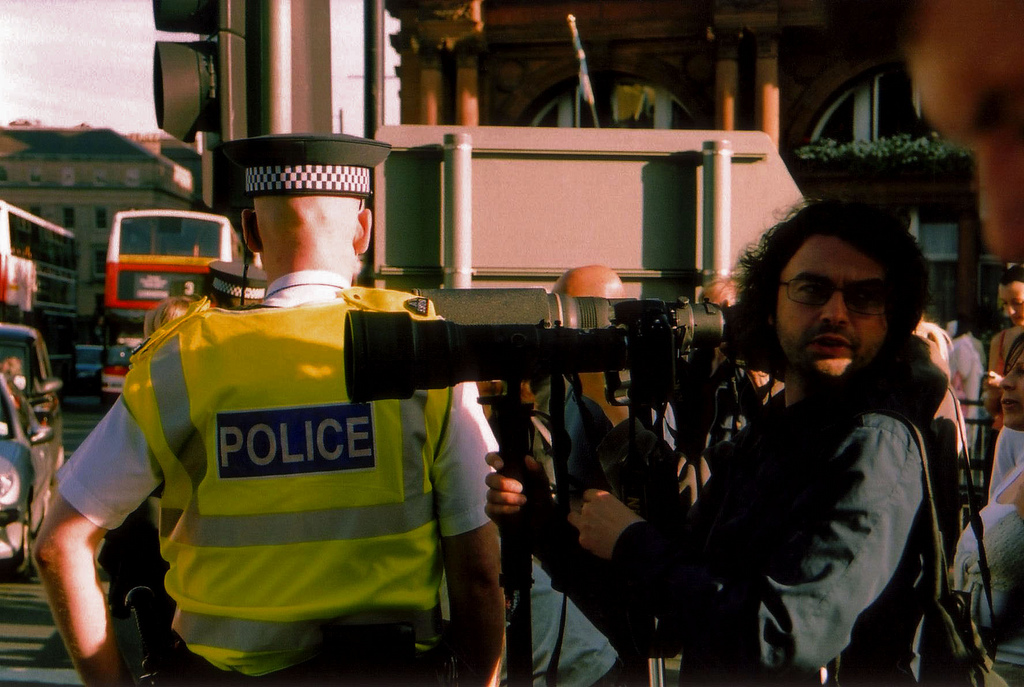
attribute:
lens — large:
[340, 300, 369, 412]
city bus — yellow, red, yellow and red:
[104, 206, 250, 343]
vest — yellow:
[118, 281, 455, 677]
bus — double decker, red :
[100, 205, 240, 398]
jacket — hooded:
[540, 352, 937, 684]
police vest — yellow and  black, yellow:
[113, 278, 458, 678]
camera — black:
[353, 231, 699, 593]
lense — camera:
[353, 338, 682, 415]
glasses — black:
[752, 268, 920, 333]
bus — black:
[73, 164, 283, 377]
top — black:
[581, 407, 1009, 683]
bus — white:
[44, 203, 272, 308]